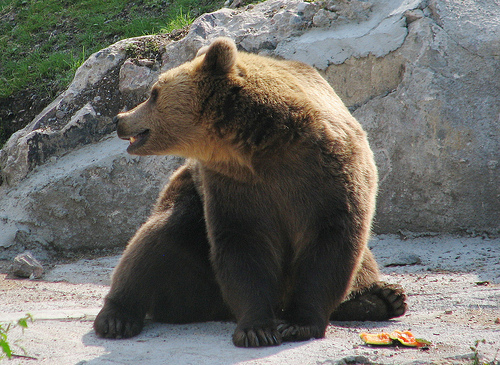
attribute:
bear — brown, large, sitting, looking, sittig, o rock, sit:
[89, 45, 410, 346]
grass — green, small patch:
[5, 1, 263, 137]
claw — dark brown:
[233, 310, 281, 351]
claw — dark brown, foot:
[97, 305, 143, 338]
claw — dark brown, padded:
[276, 301, 322, 338]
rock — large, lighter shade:
[1, 5, 499, 235]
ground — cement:
[10, 240, 497, 363]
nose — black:
[113, 112, 126, 128]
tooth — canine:
[124, 134, 136, 145]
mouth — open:
[114, 109, 158, 150]